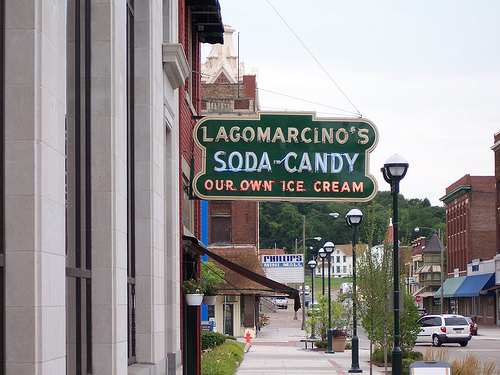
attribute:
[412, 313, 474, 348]
car — white, turning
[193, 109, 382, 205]
sign — green, lit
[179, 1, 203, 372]
store — brick, red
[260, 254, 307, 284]
sign — white, blue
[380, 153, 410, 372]
light — black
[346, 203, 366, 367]
light — black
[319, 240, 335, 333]
light — black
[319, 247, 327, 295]
light — black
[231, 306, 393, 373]
sidewalk — concrete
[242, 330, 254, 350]
fire hydrant — red, tiny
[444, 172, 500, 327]
building — brick, red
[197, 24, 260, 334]
building — red, brick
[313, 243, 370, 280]
house — white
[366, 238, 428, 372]
tree — small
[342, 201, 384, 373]
tree — small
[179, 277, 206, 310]
pot — hanging, white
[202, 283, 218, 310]
pot — hanging, white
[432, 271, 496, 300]
canopies — blue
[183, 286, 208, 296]
flowers — yellow, hanging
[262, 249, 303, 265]
word — blue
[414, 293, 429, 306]
sign — red, white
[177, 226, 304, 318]
awning — brown